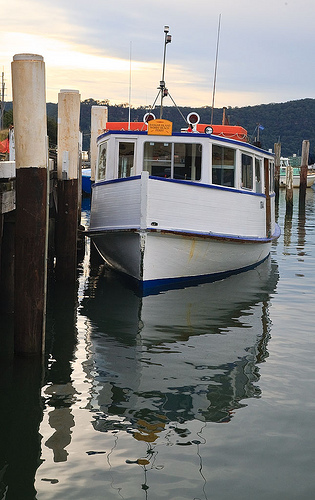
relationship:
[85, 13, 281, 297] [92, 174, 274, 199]
boat has trim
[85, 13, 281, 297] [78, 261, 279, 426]
boat has reflection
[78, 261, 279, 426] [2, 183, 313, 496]
reflection in water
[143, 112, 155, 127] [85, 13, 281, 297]
light on boat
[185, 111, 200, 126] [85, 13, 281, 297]
light on boat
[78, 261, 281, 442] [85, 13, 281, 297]
reflection of boat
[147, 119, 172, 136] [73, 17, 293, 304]
sign on boat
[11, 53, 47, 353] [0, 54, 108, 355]
pillar to dock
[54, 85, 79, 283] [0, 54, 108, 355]
pillar to dock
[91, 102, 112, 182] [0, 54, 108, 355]
pillar to dock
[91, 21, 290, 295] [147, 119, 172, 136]
boat has sign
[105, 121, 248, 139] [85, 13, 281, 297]
objects on top of a boat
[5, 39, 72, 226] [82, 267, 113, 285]
wood poles that are in water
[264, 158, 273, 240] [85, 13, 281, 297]
door of boat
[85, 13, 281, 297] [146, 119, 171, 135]
boat with a tag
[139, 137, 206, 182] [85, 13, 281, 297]
window of boat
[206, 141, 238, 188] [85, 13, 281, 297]
window of boat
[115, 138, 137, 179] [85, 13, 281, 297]
window of boat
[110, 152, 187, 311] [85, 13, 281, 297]
bow of a boat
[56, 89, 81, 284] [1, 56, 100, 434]
pillar to dock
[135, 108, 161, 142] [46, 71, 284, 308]
horn on top of boat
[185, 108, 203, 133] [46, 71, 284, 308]
horn on top of boat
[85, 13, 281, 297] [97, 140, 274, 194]
boat has windows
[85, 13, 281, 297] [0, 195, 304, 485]
boat in water